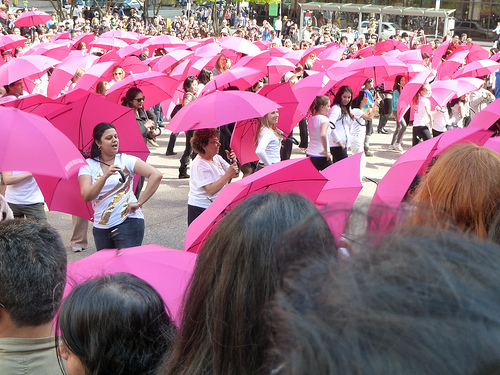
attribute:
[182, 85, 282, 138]
umbrella — pink, open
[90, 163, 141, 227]
shirt — white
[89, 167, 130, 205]
stripe — gold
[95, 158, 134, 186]
handle — dark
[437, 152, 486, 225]
hair — red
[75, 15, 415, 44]
audience — watching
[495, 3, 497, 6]
cheese — sliced